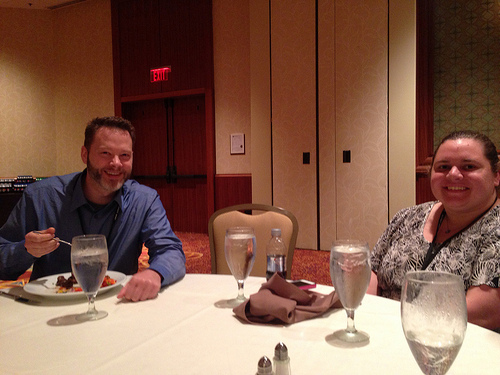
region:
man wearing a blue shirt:
[22, 117, 184, 287]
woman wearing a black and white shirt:
[373, 132, 498, 302]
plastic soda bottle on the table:
[264, 225, 290, 280]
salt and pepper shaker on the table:
[256, 345, 288, 372]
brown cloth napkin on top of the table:
[243, 277, 333, 328]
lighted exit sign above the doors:
[146, 65, 173, 80]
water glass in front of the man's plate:
[71, 235, 109, 321]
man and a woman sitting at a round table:
[8, 113, 496, 318]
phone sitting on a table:
[292, 278, 317, 290]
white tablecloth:
[111, 315, 233, 373]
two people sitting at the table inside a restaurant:
[1, 115, 498, 374]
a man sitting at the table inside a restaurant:
[1, 115, 186, 302]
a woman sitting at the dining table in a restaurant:
[364, 128, 499, 330]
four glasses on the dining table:
[69, 225, 469, 371]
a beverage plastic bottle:
[265, 228, 286, 274]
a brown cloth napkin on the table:
[232, 270, 332, 326]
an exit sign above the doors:
[146, 65, 171, 83]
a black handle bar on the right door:
[167, 170, 204, 183]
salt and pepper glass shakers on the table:
[255, 340, 291, 373]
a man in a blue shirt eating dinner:
[0, 115, 186, 302]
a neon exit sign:
[145, 65, 176, 82]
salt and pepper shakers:
[255, 339, 297, 371]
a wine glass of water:
[327, 236, 372, 346]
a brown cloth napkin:
[233, 268, 347, 331]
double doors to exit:
[119, 94, 216, 229]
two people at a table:
[3, 112, 498, 369]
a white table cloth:
[5, 270, 498, 373]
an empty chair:
[205, 200, 305, 280]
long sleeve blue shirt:
[0, 168, 187, 288]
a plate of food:
[22, 265, 131, 300]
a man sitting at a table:
[0, 113, 187, 304]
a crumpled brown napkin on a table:
[232, 270, 345, 326]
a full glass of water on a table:
[221, 228, 256, 306]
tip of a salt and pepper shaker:
[257, 343, 289, 373]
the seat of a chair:
[208, 203, 298, 280]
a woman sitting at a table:
[342, 129, 499, 332]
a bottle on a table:
[266, 228, 288, 286]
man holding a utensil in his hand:
[21, 225, 71, 257]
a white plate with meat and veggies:
[25, 268, 127, 300]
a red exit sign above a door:
[148, 67, 170, 82]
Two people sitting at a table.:
[2, 100, 495, 350]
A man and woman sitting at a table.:
[2, 102, 495, 324]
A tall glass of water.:
[315, 233, 387, 356]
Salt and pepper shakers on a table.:
[237, 336, 299, 373]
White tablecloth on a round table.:
[2, 266, 497, 372]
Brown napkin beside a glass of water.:
[218, 222, 353, 330]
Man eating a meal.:
[4, 110, 184, 305]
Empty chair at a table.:
[204, 198, 301, 278]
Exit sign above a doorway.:
[112, 58, 222, 233]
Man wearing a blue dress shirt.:
[1, 109, 188, 291]